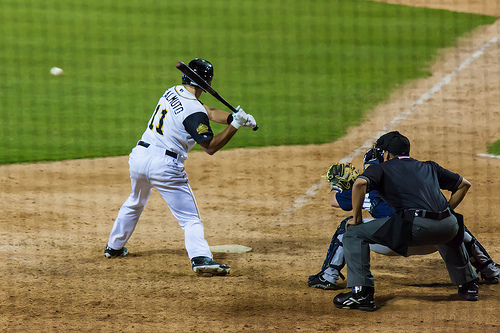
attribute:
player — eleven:
[101, 59, 257, 274]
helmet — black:
[175, 47, 222, 94]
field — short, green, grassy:
[15, 8, 487, 315]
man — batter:
[50, 24, 294, 299]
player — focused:
[100, 46, 264, 292]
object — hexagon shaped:
[204, 241, 250, 259]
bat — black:
[167, 61, 257, 127]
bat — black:
[170, 57, 260, 131]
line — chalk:
[418, 51, 485, 101]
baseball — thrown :
[48, 65, 65, 77]